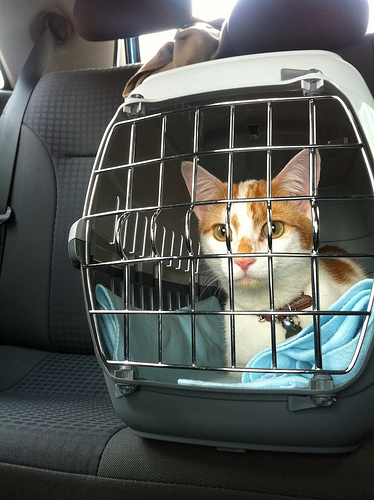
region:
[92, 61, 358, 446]
a crate on a seat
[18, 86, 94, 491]
the seat of the car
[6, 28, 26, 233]
a seat belt in the car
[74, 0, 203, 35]
the head rest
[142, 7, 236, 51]
the back window of the car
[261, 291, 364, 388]
a blue blanket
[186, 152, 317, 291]
an orange and white cat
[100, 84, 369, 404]
a cat in a crate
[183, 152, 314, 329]
a cat with a collar on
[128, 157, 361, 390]
a cat laying on a blanket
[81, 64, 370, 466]
cat in a carrying case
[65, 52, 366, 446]
animal carrying case in a car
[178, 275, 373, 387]
cat sitting on a blue blanket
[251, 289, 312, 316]
cat wearing a brown collar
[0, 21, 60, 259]
gray seatbelt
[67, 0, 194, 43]
raised, gray headrest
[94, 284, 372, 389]
blue blanket in a carrying case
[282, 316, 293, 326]
silver bell on cat's collar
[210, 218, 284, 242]
cat with two green eyes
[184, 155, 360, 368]
orange and white cat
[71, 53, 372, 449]
a cat carrier with a white top and gray bottom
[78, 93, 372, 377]
the door on a cat carrier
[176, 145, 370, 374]
an orange and white cat in a carrier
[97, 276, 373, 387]
a blue blanket in a cat carrier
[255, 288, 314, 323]
a brown leather collar on a cat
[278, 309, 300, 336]
a tag on a collar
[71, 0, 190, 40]
a headrest on a car seat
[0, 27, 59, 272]
a gray seatbelt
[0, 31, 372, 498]
a gray car seat holding a cat carrier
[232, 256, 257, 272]
a pink nose on a cat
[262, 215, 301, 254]
This cat has very green eyes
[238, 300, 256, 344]
There are steel cage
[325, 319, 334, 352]
There is a blue blanket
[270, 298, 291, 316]
There is a collar here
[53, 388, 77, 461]
The car seat here is gray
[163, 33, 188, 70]
There is a brown blanket here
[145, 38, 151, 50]
The window has a bright white color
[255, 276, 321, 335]
a cat wearing a collar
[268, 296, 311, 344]
a cat wearing a collar with a bell on it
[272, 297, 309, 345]
a cat wearing a collar with a tag on it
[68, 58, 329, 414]
a cat in a pet taxi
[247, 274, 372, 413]
a blue blanket in a pet taxi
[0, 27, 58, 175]
a seat belt inside of car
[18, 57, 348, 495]
a pet carrier inside of a car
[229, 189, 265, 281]
a cat with a pink nose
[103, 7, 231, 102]
a brown blanket on the seat of a car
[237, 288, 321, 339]
a cat wearing a brown collar with a bell on it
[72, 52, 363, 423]
a cat in a pet carrier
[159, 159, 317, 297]
the head of a cat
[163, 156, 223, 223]
the right ear of a cat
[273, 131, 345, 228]
the left ear of a cat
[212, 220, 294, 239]
the eyes of a cat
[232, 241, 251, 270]
the nose of a cat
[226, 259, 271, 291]
the mouth of a cat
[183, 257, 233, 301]
the wiskers of a cat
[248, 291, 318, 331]
the collar of a cat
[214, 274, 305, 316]
the neck of a cat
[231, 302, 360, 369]
the body of a cat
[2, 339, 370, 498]
The car seat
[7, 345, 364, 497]
A back seat in a car